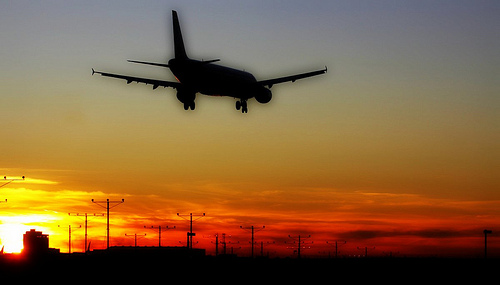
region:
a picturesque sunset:
[0, 170, 495, 282]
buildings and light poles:
[1, 140, 498, 282]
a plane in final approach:
[49, 0, 351, 272]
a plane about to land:
[50, 0, 358, 119]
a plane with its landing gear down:
[76, 7, 348, 124]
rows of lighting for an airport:
[70, 190, 360, 251]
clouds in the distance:
[0, 143, 497, 265]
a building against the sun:
[7, 209, 76, 272]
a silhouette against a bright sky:
[9, 203, 72, 265]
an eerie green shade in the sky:
[0, 101, 491, 198]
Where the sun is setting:
[2, 209, 81, 256]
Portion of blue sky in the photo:
[2, 1, 498, 63]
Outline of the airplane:
[87, 6, 330, 118]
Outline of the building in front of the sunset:
[16, 224, 66, 259]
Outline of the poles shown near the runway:
[0, 171, 498, 260]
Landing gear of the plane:
[180, 95, 251, 118]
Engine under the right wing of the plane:
[253, 83, 275, 108]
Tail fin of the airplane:
[165, 6, 187, 57]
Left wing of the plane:
[85, 60, 178, 92]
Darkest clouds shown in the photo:
[280, 221, 497, 244]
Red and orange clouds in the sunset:
[1, 168, 498, 265]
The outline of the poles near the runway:
[0, 171, 497, 260]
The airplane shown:
[81, 3, 329, 116]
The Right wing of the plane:
[252, 62, 336, 100]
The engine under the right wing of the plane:
[250, 83, 280, 106]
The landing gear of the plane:
[177, 93, 256, 116]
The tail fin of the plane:
[167, 6, 189, 63]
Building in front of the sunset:
[20, 226, 51, 256]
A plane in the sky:
[80, 0, 336, 125]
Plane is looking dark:
[84, 6, 341, 138]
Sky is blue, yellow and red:
[3, 9, 496, 252]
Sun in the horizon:
[3, 179, 101, 252]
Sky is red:
[130, 191, 499, 248]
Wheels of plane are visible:
[171, 95, 266, 121]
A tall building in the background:
[18, 224, 62, 255]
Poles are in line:
[53, 190, 405, 262]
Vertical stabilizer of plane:
[161, 5, 187, 61]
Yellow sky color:
[8, 106, 497, 167]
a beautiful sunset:
[11, 26, 468, 283]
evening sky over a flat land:
[17, 22, 497, 279]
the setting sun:
[1, 156, 91, 271]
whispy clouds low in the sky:
[11, 99, 434, 279]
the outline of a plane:
[79, 2, 359, 121]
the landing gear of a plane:
[173, 92, 259, 119]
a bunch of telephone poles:
[55, 180, 380, 272]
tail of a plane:
[126, 9, 229, 73]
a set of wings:
[92, 57, 338, 97]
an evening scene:
[42, 18, 486, 263]